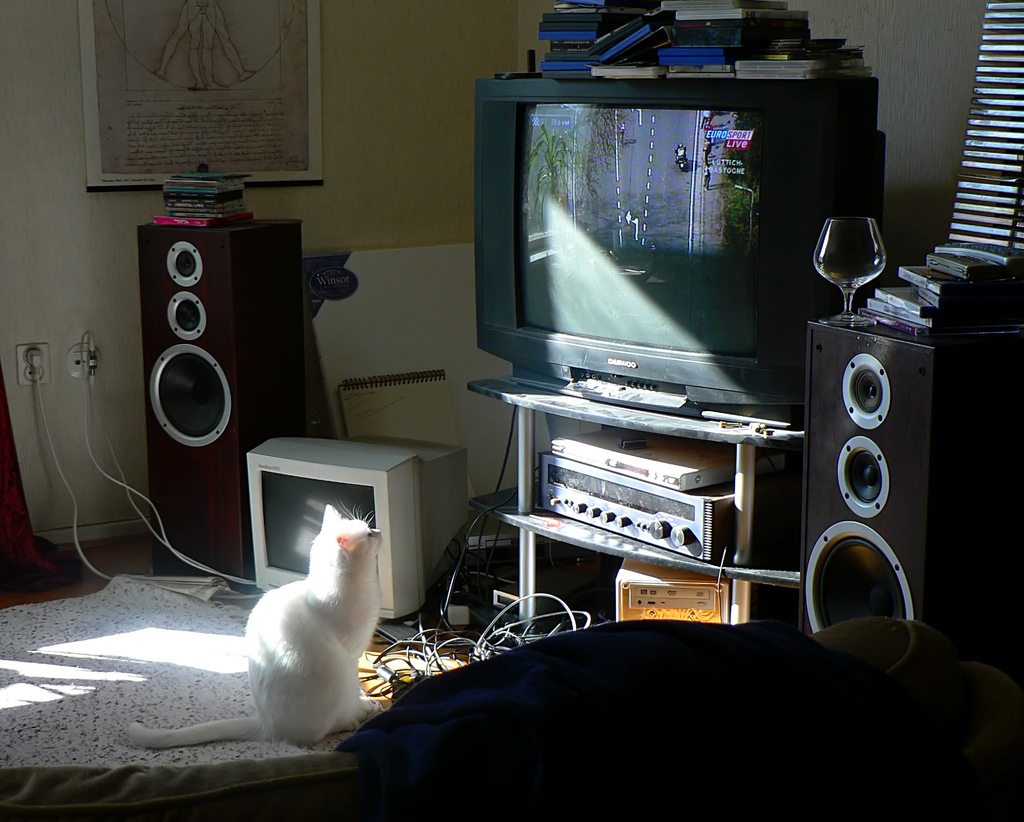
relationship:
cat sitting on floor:
[128, 499, 385, 751] [25, 539, 719, 816]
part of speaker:
[155, 237, 238, 298] [121, 192, 336, 582]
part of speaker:
[162, 280, 238, 345] [129, 204, 317, 598]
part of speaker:
[138, 339, 264, 454] [129, 204, 317, 598]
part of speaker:
[842, 356, 916, 428] [790, 302, 1009, 700]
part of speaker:
[835, 438, 903, 518] [790, 302, 1009, 700]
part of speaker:
[784, 520, 947, 650] [784, 312, 1016, 667]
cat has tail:
[117, 484, 396, 759] [114, 704, 262, 756]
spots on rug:
[1, 566, 267, 767] [1, 575, 351, 768]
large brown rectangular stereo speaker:
[138, 369, 234, 540] [133, 214, 309, 579]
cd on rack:
[946, 229, 1005, 260] [937, 0, 1022, 268]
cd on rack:
[967, 119, 1022, 133] [937, 0, 1022, 268]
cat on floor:
[117, 484, 396, 759] [1, 527, 518, 819]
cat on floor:
[117, 484, 396, 759] [1, 544, 615, 819]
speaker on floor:
[781, 278, 1021, 637] [4, 538, 623, 768]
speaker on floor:
[138, 214, 326, 580] [4, 482, 620, 766]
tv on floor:
[472, 54, 879, 422] [4, 482, 620, 766]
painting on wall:
[69, 6, 333, 207] [6, 13, 411, 351]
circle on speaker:
[132, 334, 247, 456] [121, 192, 336, 582]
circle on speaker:
[158, 285, 213, 344] [121, 192, 336, 582]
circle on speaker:
[154, 241, 209, 289] [132, 200, 329, 572]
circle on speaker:
[788, 512, 922, 638] [780, 308, 1022, 620]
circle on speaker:
[828, 427, 902, 534] [791, 296, 1018, 638]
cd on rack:
[955, 173, 1022, 195] [914, 2, 1018, 292]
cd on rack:
[940, 211, 1021, 244] [925, 6, 1021, 300]